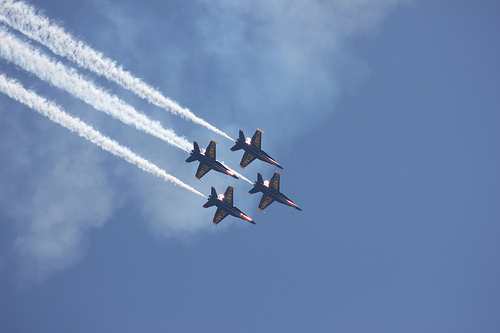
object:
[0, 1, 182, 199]
smoke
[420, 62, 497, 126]
sky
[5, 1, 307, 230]
air show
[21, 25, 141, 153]
clouds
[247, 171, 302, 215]
airplanes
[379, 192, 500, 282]
sky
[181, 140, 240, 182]
airplanes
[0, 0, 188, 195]
tracks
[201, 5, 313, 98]
sky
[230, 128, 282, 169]
jet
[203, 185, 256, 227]
jet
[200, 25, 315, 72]
clouds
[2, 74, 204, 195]
trails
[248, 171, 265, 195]
tail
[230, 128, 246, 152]
tail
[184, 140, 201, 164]
tail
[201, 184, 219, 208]
tail